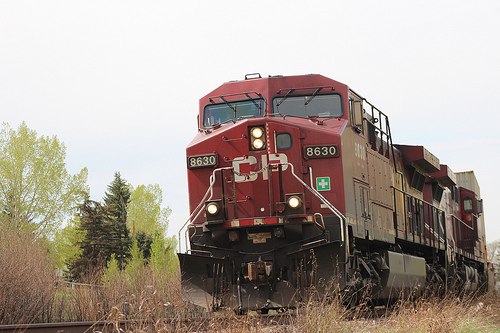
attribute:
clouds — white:
[79, 67, 137, 119]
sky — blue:
[9, 0, 495, 73]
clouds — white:
[393, 77, 441, 134]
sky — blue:
[440, 20, 498, 104]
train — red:
[331, 166, 356, 194]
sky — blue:
[74, 59, 121, 110]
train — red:
[176, 72, 489, 305]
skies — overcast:
[33, 12, 498, 73]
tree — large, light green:
[0, 124, 102, 266]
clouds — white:
[96, 39, 155, 163]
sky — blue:
[96, 132, 152, 158]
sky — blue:
[21, 1, 498, 68]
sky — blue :
[398, 29, 476, 85]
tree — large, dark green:
[64, 172, 133, 287]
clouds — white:
[62, 24, 153, 107]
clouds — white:
[409, 34, 479, 116]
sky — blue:
[22, 59, 144, 129]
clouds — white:
[68, 51, 141, 126]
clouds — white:
[0, 1, 499, 281]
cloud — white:
[299, 6, 435, 71]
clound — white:
[75, 79, 151, 152]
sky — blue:
[0, 2, 498, 242]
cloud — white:
[48, 43, 88, 101]